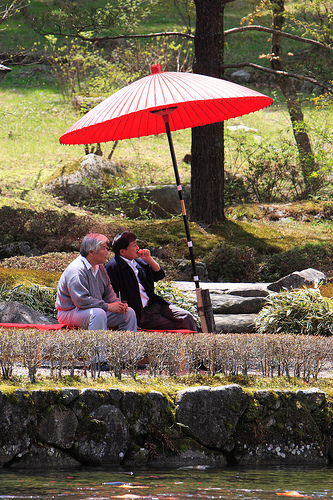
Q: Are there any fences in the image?
A: No, there are no fences.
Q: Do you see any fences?
A: No, there are no fences.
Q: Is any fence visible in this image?
A: No, there are no fences.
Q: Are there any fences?
A: No, there are no fences.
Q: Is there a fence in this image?
A: No, there are no fences.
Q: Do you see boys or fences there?
A: No, there are no fences or boys.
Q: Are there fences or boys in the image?
A: No, there are no fences or boys.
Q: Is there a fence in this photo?
A: No, there are no fences.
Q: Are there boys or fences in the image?
A: No, there are no fences or boys.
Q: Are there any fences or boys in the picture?
A: No, there are no fences or boys.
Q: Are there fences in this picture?
A: No, there are no fences.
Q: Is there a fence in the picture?
A: No, there are no fences.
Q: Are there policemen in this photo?
A: No, there are no policemen.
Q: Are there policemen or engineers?
A: No, there are no policemen or engineers.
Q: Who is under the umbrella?
A: The man is under the umbrella.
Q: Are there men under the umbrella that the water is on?
A: Yes, there is a man under the umbrella.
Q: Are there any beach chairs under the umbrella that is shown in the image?
A: No, there is a man under the umbrella.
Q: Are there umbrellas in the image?
A: Yes, there is an umbrella.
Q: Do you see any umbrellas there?
A: Yes, there is an umbrella.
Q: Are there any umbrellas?
A: Yes, there is an umbrella.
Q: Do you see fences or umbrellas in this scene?
A: Yes, there is an umbrella.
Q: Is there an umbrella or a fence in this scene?
A: Yes, there is an umbrella.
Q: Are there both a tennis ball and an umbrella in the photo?
A: No, there is an umbrella but no tennis balls.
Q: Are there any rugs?
A: No, there are no rugs.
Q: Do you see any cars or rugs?
A: No, there are no rugs or cars.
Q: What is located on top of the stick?
A: The umbrella is on top of the stick.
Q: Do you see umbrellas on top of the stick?
A: Yes, there is an umbrella on top of the stick.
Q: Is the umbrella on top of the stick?
A: Yes, the umbrella is on top of the stick.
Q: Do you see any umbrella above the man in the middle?
A: Yes, there is an umbrella above the man.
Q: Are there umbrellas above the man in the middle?
A: Yes, there is an umbrella above the man.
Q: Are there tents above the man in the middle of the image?
A: No, there is an umbrella above the man.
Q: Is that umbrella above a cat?
A: No, the umbrella is above a man.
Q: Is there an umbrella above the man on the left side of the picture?
A: Yes, there is an umbrella above the man.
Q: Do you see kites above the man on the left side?
A: No, there is an umbrella above the man.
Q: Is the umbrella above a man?
A: Yes, the umbrella is above a man.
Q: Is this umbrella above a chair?
A: No, the umbrella is above a man.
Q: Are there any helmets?
A: No, there are no helmets.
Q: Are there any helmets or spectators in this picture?
A: No, there are no helmets or spectators.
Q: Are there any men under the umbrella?
A: Yes, there is a man under the umbrella.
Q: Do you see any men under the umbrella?
A: Yes, there is a man under the umbrella.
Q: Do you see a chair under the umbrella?
A: No, there is a man under the umbrella.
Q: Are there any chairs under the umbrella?
A: No, there is a man under the umbrella.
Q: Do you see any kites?
A: No, there are no kites.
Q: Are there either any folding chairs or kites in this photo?
A: No, there are no kites or folding chairs.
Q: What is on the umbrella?
A: The water is on the umbrella.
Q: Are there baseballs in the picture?
A: No, there are no baseballs.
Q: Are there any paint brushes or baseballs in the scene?
A: No, there are no baseballs or paint brushes.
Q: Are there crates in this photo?
A: No, there are no crates.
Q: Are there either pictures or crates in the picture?
A: No, there are no crates or pictures.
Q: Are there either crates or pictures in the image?
A: No, there are no crates or pictures.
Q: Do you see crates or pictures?
A: No, there are no crates or pictures.